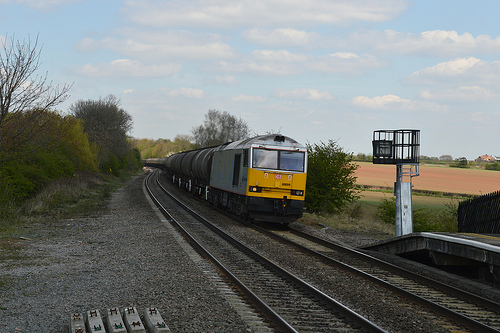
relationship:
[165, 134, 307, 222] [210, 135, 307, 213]
train has car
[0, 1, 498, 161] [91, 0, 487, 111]
sky has clouds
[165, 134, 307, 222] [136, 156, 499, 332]
train on top of tracks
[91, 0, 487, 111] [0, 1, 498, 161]
clouds in sky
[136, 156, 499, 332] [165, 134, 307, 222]
tracks under train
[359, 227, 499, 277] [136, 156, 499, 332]
ramp next to tracks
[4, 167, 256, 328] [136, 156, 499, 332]
stones under tracks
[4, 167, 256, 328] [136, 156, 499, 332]
stones next to tracks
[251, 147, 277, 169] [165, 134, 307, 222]
window on train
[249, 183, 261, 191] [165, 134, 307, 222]
headlight on train